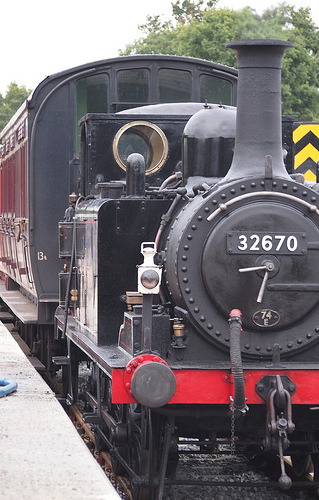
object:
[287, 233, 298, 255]
number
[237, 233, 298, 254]
number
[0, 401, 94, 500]
platform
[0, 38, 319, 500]
train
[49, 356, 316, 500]
track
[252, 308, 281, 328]
number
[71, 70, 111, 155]
window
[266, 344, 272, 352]
black hose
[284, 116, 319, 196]
sign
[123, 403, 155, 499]
wheel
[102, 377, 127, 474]
wheel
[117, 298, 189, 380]
giraffe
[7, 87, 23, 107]
trees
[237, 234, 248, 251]
number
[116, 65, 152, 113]
windows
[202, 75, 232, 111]
window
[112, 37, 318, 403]
front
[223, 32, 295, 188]
smoke stack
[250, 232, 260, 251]
number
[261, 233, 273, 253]
number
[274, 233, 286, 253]
number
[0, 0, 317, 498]
photo